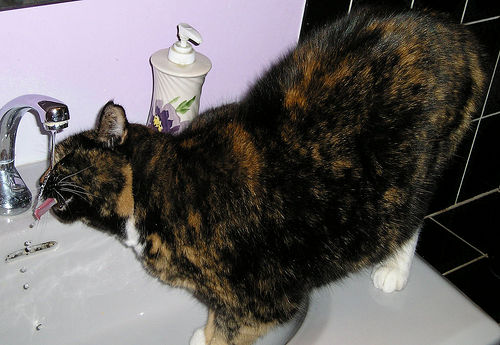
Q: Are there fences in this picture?
A: No, there are no fences.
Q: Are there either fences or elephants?
A: No, there are no fences or elephants.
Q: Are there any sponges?
A: No, there are no sponges.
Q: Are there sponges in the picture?
A: No, there are no sponges.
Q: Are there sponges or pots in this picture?
A: No, there are no sponges or pots.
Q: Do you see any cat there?
A: Yes, there is a cat.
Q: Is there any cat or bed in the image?
A: Yes, there is a cat.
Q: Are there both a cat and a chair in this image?
A: No, there is a cat but no chairs.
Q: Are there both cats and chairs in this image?
A: No, there is a cat but no chairs.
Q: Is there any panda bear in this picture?
A: No, there are no panda bears.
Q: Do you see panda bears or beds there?
A: No, there are no panda bears or beds.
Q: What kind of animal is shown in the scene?
A: The animal is a cat.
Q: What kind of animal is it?
A: The animal is a cat.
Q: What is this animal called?
A: This is a cat.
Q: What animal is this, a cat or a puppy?
A: This is a cat.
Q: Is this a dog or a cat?
A: This is a cat.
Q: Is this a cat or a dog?
A: This is a cat.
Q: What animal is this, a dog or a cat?
A: This is a cat.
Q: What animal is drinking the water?
A: The cat is drinking the water.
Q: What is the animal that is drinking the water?
A: The animal is a cat.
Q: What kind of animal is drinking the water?
A: The animal is a cat.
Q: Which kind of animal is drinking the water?
A: The animal is a cat.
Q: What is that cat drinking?
A: The cat is drinking water.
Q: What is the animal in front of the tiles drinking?
A: The cat is drinking water.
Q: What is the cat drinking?
A: The cat is drinking water.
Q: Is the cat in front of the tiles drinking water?
A: Yes, the cat is drinking water.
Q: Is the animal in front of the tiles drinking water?
A: Yes, the cat is drinking water.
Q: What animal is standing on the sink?
A: The cat is standing on the sink.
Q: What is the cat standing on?
A: The cat is standing on the sink.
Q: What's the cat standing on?
A: The cat is standing on the sink.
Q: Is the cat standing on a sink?
A: Yes, the cat is standing on a sink.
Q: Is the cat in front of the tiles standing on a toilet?
A: No, the cat is standing on a sink.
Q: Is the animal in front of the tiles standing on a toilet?
A: No, the cat is standing on a sink.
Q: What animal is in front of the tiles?
A: The cat is in front of the tiles.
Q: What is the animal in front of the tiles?
A: The animal is a cat.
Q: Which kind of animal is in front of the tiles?
A: The animal is a cat.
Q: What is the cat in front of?
A: The cat is in front of the tiles.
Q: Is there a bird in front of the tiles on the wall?
A: No, there is a cat in front of the tiles.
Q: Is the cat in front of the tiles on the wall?
A: Yes, the cat is in front of the tiles.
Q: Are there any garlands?
A: No, there are no garlands.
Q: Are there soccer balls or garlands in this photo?
A: No, there are no garlands or soccer balls.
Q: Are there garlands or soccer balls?
A: No, there are no garlands or soccer balls.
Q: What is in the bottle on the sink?
A: The liquid is in the bottle.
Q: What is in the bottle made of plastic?
A: The liquid is in the bottle.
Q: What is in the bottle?
A: The liquid is in the bottle.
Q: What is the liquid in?
A: The liquid is in the bottle.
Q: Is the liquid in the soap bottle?
A: Yes, the liquid is in the bottle.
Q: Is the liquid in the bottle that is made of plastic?
A: Yes, the liquid is in the bottle.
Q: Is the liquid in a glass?
A: No, the liquid is in the bottle.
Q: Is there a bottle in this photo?
A: Yes, there is a bottle.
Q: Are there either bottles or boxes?
A: Yes, there is a bottle.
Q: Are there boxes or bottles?
A: Yes, there is a bottle.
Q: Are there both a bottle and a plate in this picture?
A: No, there is a bottle but no plates.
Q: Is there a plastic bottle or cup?
A: Yes, there is a plastic bottle.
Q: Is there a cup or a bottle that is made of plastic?
A: Yes, the bottle is made of plastic.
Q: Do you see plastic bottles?
A: Yes, there is a bottle that is made of plastic.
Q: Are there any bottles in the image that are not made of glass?
A: Yes, there is a bottle that is made of plastic.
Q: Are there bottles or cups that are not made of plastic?
A: No, there is a bottle but it is made of plastic.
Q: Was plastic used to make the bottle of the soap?
A: Yes, the bottle is made of plastic.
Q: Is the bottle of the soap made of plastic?
A: Yes, the bottle is made of plastic.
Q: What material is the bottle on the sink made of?
A: The bottle is made of plastic.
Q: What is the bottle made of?
A: The bottle is made of plastic.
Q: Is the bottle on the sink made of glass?
A: No, the bottle is made of plastic.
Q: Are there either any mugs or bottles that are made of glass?
A: No, there is a bottle but it is made of plastic.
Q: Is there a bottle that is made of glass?
A: No, there is a bottle but it is made of plastic.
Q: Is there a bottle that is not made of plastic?
A: No, there is a bottle but it is made of plastic.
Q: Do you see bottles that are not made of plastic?
A: No, there is a bottle but it is made of plastic.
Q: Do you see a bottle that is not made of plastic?
A: No, there is a bottle but it is made of plastic.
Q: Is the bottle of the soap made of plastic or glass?
A: The bottle is made of plastic.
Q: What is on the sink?
A: The bottle is on the sink.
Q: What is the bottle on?
A: The bottle is on the sink.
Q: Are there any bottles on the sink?
A: Yes, there is a bottle on the sink.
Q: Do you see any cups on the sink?
A: No, there is a bottle on the sink.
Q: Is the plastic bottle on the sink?
A: Yes, the bottle is on the sink.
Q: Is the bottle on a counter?
A: No, the bottle is on the sink.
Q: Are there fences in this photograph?
A: No, there are no fences.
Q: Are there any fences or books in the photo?
A: No, there are no fences or books.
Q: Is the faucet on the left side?
A: Yes, the faucet is on the left of the image.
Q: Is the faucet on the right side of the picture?
A: No, the faucet is on the left of the image.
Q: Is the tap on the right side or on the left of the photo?
A: The tap is on the left of the image.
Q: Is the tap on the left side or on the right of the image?
A: The tap is on the left of the image.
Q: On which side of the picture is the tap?
A: The tap is on the left of the image.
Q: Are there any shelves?
A: No, there are no shelves.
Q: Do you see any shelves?
A: No, there are no shelves.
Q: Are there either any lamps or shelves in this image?
A: No, there are no shelves or lamps.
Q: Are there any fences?
A: No, there are no fences.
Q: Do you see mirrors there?
A: No, there are no mirrors.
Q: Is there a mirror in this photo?
A: No, there are no mirrors.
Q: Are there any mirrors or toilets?
A: No, there are no mirrors or toilets.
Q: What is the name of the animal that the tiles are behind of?
A: The animal is a cat.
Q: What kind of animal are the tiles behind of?
A: The tiles are behind the cat.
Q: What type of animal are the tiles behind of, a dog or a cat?
A: The tiles are behind a cat.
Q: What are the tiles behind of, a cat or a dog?
A: The tiles are behind a cat.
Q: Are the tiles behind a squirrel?
A: No, the tiles are behind a cat.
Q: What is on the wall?
A: The tiles are on the wall.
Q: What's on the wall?
A: The tiles are on the wall.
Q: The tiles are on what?
A: The tiles are on the wall.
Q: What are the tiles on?
A: The tiles are on the wall.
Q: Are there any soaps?
A: Yes, there is a soap.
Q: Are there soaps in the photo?
A: Yes, there is a soap.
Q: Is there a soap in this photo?
A: Yes, there is a soap.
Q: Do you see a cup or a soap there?
A: Yes, there is a soap.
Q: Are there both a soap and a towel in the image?
A: No, there is a soap but no towels.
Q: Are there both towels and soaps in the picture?
A: No, there is a soap but no towels.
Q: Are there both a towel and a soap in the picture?
A: No, there is a soap but no towels.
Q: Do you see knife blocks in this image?
A: No, there are no knife blocks.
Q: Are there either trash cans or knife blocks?
A: No, there are no knife blocks or trash cans.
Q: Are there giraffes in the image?
A: No, there are no giraffes.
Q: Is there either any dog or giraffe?
A: No, there are no giraffes or dogs.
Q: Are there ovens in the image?
A: No, there are no ovens.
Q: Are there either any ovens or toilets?
A: No, there are no ovens or toilets.